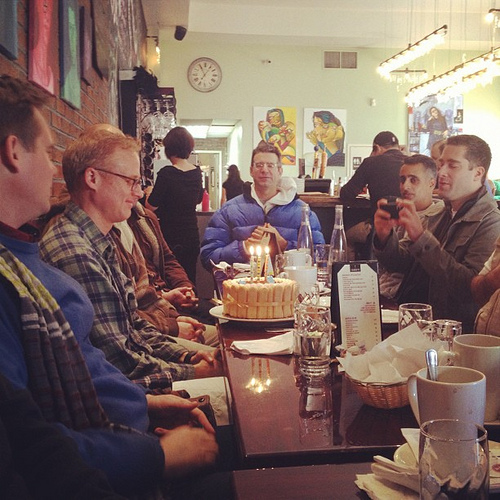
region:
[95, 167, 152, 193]
Eyeglasses in the photo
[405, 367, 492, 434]
A cup in the photo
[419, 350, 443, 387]
A spoon in the photo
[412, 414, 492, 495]
A glass in the photo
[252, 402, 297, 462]
A table in the photo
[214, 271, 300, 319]
A cake in the photo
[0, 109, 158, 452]
People seated in the room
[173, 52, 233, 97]
A clock on the wall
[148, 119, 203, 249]
A woman standing in the room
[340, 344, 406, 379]
Serviettes in the photo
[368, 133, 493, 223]
the man is taking a picture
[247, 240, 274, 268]
the candles are lite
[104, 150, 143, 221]
the man is smiling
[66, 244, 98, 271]
the shirt is plaid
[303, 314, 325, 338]
the glass is clear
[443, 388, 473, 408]
the cup is white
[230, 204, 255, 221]
the coat is blue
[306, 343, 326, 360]
the liquid is clear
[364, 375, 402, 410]
the basket is woven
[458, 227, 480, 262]
the coat is gray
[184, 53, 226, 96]
The clock on the wall.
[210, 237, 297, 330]
A birthday candle on the table.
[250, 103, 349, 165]
Two pieces of art hanging on the wall next to each other.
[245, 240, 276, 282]
Three candles on a cake.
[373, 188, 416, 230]
A camera being held by a man.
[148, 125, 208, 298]
A lady wearing a black dress.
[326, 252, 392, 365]
A menu propped up on the table.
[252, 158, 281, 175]
Eyeglasses being worn by a man in a blue coat.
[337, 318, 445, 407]
An empty bread basket.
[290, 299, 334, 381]
A glass of water close to a standing menu.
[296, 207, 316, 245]
this is a bottle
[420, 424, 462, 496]
this is a glass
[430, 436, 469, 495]
the glass is shinny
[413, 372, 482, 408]
this is a cup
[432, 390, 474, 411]
the cup is white in color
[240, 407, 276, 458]
this is the table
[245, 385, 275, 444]
the table is brown in color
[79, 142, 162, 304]
this is a man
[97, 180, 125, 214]
the man is light skinned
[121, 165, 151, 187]
this is a spectacle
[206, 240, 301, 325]
Birthday cake on a table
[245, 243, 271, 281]
Three lit candles on a cake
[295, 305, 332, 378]
Glass half full with water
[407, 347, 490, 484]
Mug with spoon inside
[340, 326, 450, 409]
Empty basket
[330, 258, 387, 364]
Wine menu on top of a table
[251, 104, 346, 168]
Paintings on the wall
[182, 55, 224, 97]
Clock hanging on the wall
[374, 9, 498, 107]
Lights hanging from the ceiling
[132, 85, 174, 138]
Glasses hanging above the bar